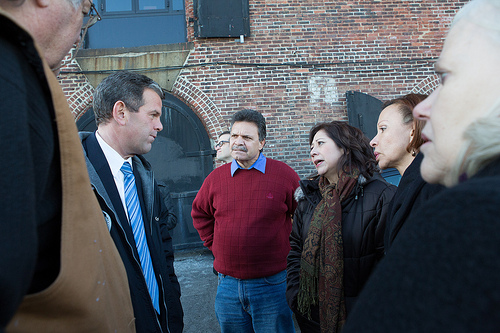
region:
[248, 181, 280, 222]
maroon logo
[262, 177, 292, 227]
maroon logo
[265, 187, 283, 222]
maroon logo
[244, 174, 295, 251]
maroon logo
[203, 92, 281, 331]
this is a man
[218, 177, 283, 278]
the sweater is red in color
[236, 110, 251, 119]
the hair is short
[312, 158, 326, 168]
the mouth is open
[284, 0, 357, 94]
this is the wall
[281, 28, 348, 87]
the wall is made of bricks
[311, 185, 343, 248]
she is tying s scrf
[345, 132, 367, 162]
the hair is long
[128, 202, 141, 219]
the neck tie is blue in color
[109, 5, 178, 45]
the window is closed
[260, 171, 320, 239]
maroon logo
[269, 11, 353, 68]
bricks of building wall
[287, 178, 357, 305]
long scarf around neck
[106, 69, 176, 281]
man in striped tie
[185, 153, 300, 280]
red sweater on man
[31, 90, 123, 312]
brown vest on man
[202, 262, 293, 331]
blue jeans on man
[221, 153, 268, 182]
blue collar on man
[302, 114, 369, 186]
woman with tilted head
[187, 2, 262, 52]
black shutter on building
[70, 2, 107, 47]
glasses on man's face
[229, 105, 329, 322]
A man in red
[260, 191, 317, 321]
A man in red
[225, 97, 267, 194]
A man in red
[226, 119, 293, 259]
A man in red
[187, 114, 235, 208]
A man in red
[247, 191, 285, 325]
A man in red